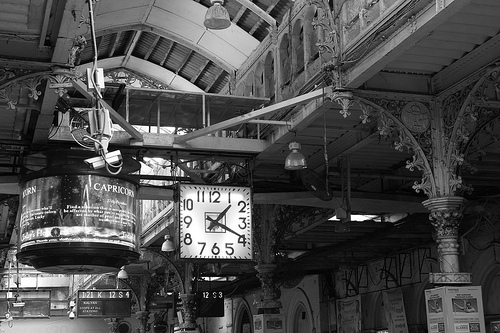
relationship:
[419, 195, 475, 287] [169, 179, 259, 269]
pillar by clock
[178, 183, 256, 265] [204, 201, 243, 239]
clock with hands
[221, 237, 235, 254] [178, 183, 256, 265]
number on clock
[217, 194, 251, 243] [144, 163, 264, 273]
hand on clock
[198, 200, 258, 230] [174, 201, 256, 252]
hand on clock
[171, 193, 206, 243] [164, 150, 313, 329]
nine on clock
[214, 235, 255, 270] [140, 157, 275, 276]
number on clock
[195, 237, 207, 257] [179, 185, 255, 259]
number on face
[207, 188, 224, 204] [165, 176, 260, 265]
number on face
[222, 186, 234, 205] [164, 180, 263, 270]
number on face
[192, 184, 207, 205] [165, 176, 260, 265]
number on face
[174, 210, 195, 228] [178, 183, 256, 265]
number on clock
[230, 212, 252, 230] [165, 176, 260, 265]
number on face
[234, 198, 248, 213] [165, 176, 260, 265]
number on face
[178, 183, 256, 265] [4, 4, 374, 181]
clock on ceiling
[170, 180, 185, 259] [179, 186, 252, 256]
frame around clock